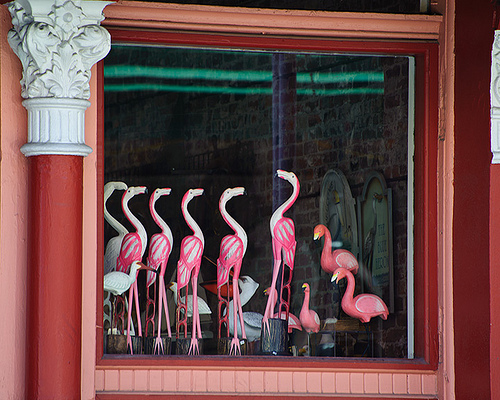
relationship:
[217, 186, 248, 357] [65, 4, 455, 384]
bird in front of window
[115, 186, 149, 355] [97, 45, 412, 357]
bird in front of window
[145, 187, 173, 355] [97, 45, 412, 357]
flamingo displayed in front of window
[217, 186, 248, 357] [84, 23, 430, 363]
bird in front of display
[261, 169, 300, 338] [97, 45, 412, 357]
bird in front of window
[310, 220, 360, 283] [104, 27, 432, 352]
bird in front of window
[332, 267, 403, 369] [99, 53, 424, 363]
bird in front of window display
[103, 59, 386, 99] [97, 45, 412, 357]
reflection in window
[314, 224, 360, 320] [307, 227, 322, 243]
bird has beak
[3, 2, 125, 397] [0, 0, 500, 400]
column on bad statement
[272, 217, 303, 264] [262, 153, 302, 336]
wing on flamingo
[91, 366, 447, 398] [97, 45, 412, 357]
brick on bottom of window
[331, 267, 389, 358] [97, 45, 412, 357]
bird in window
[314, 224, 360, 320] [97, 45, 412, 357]
bird in window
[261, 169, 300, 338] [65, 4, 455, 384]
bird in window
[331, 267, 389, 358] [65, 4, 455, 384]
bird in window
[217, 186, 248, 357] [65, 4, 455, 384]
bird in window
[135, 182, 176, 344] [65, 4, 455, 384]
flamingo in window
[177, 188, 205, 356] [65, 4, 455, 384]
flamingo in window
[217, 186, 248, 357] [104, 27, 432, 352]
bird in window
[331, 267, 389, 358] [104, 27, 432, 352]
bird in window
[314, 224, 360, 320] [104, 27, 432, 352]
bird in window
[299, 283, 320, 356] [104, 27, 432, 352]
bird in window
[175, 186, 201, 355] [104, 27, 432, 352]
flamingo in window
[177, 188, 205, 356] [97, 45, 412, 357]
flamingo in window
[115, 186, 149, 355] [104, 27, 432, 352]
bird in window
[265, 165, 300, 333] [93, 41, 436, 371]
bird in window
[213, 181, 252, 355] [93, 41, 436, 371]
bird in window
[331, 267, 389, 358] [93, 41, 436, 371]
bird in window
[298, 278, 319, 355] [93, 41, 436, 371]
bird in window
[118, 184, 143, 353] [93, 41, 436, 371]
bird in window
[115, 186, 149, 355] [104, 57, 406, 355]
bird on glass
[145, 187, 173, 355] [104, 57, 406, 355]
flamingo on glass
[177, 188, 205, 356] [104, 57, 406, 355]
flamingo on glass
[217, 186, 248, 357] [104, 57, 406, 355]
bird on glass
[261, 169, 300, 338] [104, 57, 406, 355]
bird on glass